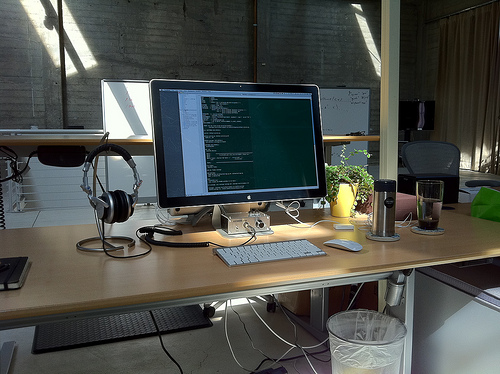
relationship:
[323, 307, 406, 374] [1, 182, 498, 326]
basket under desk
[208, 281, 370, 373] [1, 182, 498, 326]
cords are under desk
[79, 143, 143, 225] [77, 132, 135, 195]
headphones on a stand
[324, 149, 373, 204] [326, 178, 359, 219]
plant in a pot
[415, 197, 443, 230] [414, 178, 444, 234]
water in a glass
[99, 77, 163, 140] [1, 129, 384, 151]
whiteboard behind desk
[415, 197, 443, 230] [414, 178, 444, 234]
water in glass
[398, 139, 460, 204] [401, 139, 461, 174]
chair has a back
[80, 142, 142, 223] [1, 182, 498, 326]
headphones are on desk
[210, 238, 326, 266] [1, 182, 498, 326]
keyboard on desk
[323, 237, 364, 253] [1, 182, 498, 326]
mouse on desk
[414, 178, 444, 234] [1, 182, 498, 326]
glass on desk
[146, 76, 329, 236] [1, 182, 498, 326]
computer on desk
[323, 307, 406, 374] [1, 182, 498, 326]
can under desk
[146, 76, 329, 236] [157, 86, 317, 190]
computer has a screen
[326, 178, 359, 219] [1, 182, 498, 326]
pot on desk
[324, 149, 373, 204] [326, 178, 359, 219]
plant in pot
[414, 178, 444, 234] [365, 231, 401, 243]
glass on a coaster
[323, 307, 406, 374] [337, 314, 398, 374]
basket has lining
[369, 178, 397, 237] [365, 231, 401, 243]
container sitting on a coaster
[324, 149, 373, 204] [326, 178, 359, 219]
plant in a vase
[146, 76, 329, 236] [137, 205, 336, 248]
computer has wires